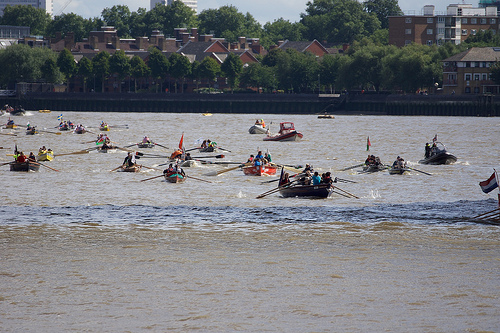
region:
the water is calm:
[78, 238, 235, 315]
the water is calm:
[71, 168, 246, 323]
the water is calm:
[129, 248, 293, 325]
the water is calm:
[186, 241, 259, 330]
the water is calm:
[155, 233, 247, 319]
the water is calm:
[161, 262, 232, 329]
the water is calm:
[136, 223, 218, 328]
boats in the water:
[46, 58, 457, 200]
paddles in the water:
[327, 179, 361, 213]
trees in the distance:
[248, 44, 348, 90]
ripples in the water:
[184, 206, 244, 251]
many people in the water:
[75, 106, 402, 251]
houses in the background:
[121, 21, 276, 86]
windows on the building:
[460, 11, 480, 41]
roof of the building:
[184, 36, 217, 53]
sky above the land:
[261, 3, 293, 18]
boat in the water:
[268, 126, 310, 150]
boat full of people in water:
[255, 160, 360, 223]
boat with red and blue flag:
[356, 131, 386, 186]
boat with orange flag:
[165, 132, 201, 169]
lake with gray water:
[62, 177, 343, 321]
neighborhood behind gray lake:
[65, 15, 337, 74]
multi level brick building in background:
[378, 2, 491, 72]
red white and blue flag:
[469, 161, 499, 213]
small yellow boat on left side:
[32, 141, 60, 171]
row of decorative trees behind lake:
[52, 49, 427, 96]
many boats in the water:
[4, 107, 476, 204]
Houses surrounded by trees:
[18, 13, 335, 86]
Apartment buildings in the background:
[383, 3, 499, 105]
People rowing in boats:
[278, 163, 338, 200]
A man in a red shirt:
[8, 145, 31, 172]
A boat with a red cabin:
[263, 118, 305, 145]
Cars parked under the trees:
[174, 80, 234, 96]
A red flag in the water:
[361, 132, 377, 154]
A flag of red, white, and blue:
[477, 164, 497, 208]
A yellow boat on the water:
[36, 143, 57, 163]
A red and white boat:
[238, 160, 280, 179]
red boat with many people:
[236, 150, 280, 179]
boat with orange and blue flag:
[355, 132, 383, 177]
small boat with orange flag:
[167, 130, 193, 170]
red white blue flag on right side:
[472, 159, 498, 219]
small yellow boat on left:
[28, 138, 63, 168]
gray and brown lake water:
[23, 198, 292, 328]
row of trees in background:
[53, 48, 432, 103]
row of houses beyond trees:
[55, 21, 332, 66]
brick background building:
[381, 6, 497, 51]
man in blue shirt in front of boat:
[305, 163, 325, 188]